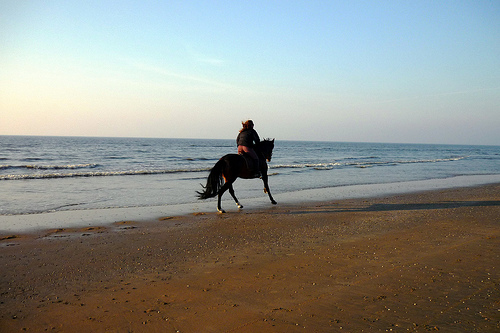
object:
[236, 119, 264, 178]
woman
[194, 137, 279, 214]
horse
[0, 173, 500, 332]
beach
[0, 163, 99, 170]
waves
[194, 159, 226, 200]
tail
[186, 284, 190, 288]
pebbles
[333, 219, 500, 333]
sand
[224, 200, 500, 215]
shadow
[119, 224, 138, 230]
footprints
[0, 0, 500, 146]
sky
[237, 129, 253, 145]
back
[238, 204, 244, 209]
hoof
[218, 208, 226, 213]
hoof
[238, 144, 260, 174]
pants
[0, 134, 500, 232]
ocean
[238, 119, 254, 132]
hair